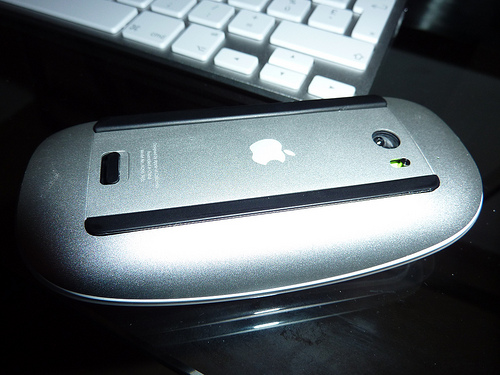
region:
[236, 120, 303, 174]
a white apple logo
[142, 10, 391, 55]
keys on a board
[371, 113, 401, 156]
a round clear circle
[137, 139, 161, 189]
some white letters on a machine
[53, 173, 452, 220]
a long black line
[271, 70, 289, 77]
a black letter on a keyboard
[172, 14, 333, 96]
the keys are white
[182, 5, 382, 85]
the keys are white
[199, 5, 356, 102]
the keys are white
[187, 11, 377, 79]
the keys are white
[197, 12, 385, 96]
the keys are white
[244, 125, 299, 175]
the logo is Apple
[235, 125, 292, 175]
the logo is Apple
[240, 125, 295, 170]
the logo is Apple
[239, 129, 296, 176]
the logo is Apple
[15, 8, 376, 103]
the corner of a keyboard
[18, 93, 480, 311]
a silver iphone case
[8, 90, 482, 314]
a gray phone in a cover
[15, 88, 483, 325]
an apple product on the tabletop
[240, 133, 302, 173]
a white apple logo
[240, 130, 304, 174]
the apple icon on a phone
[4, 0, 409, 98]
a thin white keyboard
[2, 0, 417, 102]
a gray keyboard with white keys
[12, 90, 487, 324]
a rounded thick phone case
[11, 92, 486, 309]
an upside down Apple Magic Mouse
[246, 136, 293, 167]
white Apple corporate logo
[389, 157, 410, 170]
an on off switch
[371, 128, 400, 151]
a mouse tracking sensor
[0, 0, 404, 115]
an Apple wireless keyboard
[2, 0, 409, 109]
a bluetooth computer keyboard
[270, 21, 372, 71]
a computer shift key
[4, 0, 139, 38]
a computer space bar key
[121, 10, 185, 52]
an Apple command key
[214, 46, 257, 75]
a left arrow key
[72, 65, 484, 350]
a mouse that is on a table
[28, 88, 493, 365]
a silver mouse on table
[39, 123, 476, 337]
an apple mouse on table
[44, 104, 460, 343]
a mouse upside down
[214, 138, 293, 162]
a white apple on mouse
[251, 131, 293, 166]
an apple on mouse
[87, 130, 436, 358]
a mouse is upside down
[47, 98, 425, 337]
a silver mouse upsdie down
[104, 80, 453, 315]
a silver apple mouse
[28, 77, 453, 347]
a silver apple mouse upside down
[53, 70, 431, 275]
a mouse on the table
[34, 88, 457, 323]
a silver mouse on the table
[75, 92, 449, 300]
an apple mouse on teh table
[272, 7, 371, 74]
a key on a keyboard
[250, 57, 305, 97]
a key on a keyboard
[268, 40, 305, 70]
a key on a keyboard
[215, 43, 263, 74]
a key on a keyboard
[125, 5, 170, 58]
a key on a keyboard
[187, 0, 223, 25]
a key on a keyboard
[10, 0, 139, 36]
a key on a keyboard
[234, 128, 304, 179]
the logo of the company Apple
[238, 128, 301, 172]
the Apple logo is white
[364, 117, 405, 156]
a camera on a cell phone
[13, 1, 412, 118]
keyboard with white buttons